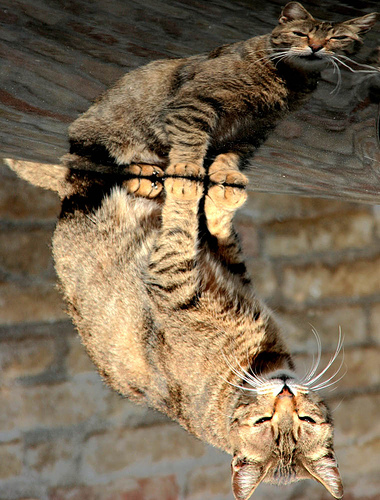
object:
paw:
[121, 163, 165, 178]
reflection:
[0, 4, 380, 192]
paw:
[163, 174, 206, 197]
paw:
[122, 175, 163, 196]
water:
[1, 168, 380, 497]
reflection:
[0, 174, 377, 500]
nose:
[276, 383, 295, 398]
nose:
[308, 40, 324, 52]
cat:
[63, 0, 378, 182]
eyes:
[293, 29, 310, 37]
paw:
[209, 171, 250, 186]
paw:
[207, 183, 249, 206]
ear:
[231, 453, 272, 499]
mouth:
[271, 372, 294, 383]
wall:
[64, 19, 130, 68]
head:
[270, 0, 379, 76]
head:
[228, 370, 346, 499]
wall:
[0, 178, 379, 500]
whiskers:
[212, 322, 349, 393]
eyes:
[330, 34, 351, 41]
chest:
[223, 69, 287, 116]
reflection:
[59, 0, 380, 183]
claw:
[165, 162, 206, 177]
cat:
[48, 182, 350, 497]